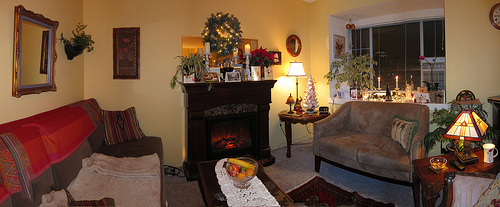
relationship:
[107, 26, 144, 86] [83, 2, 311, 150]
picture on wall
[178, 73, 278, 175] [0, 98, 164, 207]
fireplace on couch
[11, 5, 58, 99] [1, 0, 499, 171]
mirror on wall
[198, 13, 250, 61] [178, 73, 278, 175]
wreath over fireplace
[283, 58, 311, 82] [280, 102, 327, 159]
lamp on table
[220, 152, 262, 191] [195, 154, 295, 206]
bowl on table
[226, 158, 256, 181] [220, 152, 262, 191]
fruit in bowl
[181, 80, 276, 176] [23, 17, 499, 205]
fireplace in living room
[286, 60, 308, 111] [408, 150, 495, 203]
lamp on end table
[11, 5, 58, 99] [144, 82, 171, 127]
mirror on wall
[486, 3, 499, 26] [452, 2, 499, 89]
clock on wall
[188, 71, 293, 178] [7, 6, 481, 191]
fireplace in living room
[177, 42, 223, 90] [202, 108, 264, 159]
pot plant on top of fire place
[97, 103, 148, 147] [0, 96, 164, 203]
pillow on couch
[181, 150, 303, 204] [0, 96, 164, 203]
table in front of couch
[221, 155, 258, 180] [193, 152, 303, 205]
fruit on coffee table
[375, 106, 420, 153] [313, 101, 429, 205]
pillow on couch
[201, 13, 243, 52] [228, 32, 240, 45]
wreath has lights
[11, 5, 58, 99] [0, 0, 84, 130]
mirror on wall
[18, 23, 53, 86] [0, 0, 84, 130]
mirror on wall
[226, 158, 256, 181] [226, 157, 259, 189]
fruit in bowl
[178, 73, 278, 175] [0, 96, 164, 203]
fireplace on couch